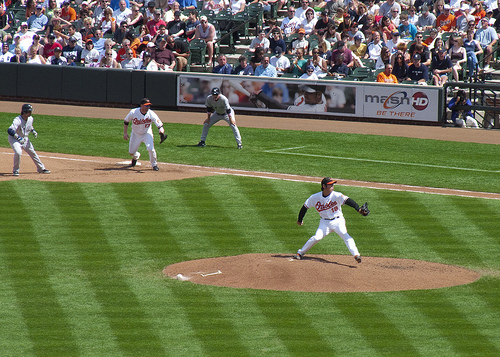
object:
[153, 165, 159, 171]
shoe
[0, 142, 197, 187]
first base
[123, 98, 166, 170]
baseball player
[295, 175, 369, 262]
baseball player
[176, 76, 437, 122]
advertisement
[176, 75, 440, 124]
billboard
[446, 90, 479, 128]
man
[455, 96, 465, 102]
camera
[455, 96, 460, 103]
hand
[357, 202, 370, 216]
glove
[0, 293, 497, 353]
grass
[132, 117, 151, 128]
letters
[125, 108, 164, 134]
jersey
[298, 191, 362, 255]
uniform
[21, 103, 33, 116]
helmet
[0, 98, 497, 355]
baseball field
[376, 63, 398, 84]
man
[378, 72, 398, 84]
orange shirt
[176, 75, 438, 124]
sign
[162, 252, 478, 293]
dirt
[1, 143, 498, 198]
dirt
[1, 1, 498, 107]
spectators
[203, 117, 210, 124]
hand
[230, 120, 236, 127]
hand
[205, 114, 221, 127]
thigh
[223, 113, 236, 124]
thigh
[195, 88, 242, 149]
baseball player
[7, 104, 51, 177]
baseball player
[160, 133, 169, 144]
glove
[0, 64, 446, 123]
wall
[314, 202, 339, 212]
name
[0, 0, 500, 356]
picture